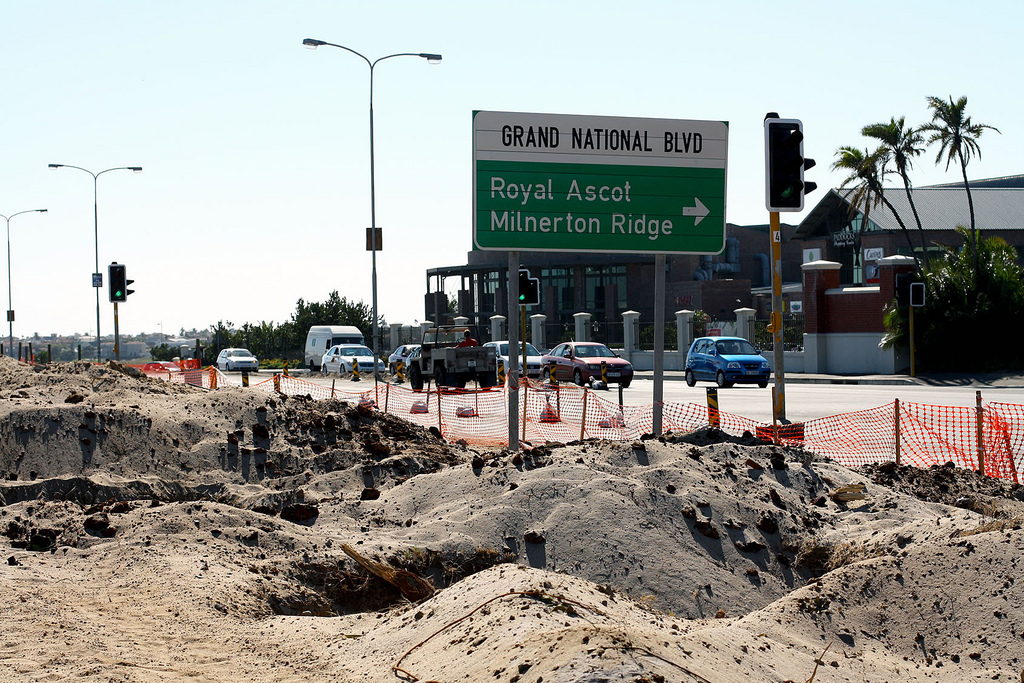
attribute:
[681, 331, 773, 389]
car — blue, compact, small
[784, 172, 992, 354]
building — side 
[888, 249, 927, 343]
wall — side 